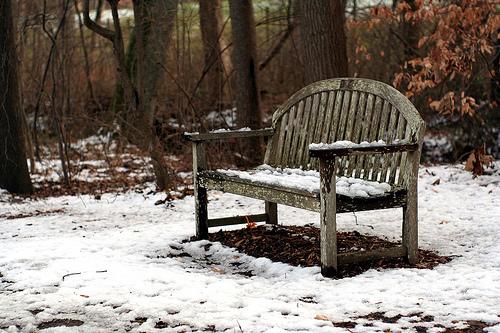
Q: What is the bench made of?
A: Wood.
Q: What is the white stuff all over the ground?
A: Snow.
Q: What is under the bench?
A: Leaves.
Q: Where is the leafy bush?
A: Top right.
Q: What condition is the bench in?
A: Old and chipping.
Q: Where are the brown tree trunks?
A: Behind the bench.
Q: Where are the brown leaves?
A: On the tree.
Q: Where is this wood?
A: On the bench.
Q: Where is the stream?
A: Behind the trees.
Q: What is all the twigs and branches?
A: Undergrowth.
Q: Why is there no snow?
A: Bench blocked snow.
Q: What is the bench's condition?
A: The bench is old.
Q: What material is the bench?
A: Its wooden.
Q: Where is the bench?
A: In the woods.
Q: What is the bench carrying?
A: White snow.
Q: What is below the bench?
A: Dry leaves.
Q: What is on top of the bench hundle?
A: White snow.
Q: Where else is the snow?
A: In the field around the bench.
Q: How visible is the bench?
A: Very visible.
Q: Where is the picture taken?
A: A park.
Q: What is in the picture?
A: A bench.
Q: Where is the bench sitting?
A: In the forest.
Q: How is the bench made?
A: Of wood.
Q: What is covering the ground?
A: Snow.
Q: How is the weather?
A: Sunny.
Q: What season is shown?
A: Winter.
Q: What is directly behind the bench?
A: Trees.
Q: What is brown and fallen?
A: Leaves.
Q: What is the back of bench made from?
A: Slats.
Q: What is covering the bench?
A: Snow.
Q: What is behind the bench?
A: Trees.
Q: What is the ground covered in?
A: Snow.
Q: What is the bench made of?
A: Wood.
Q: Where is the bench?
A: In the forest.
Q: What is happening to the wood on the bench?
A: It is slightly eroding.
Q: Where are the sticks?
A: On the ground.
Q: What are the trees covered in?
A: Bark.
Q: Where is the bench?
A: In the snow.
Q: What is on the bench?
A: Snow.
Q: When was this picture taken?
A: Winter.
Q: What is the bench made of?
A: Wood.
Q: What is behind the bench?
A: Trees.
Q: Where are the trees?
A: Behind the bench.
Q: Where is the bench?
A: In the snow.